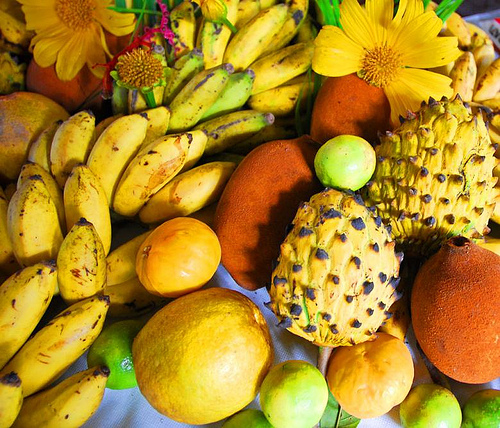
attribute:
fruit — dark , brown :
[190, 139, 437, 338]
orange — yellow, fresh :
[134, 215, 221, 295]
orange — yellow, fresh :
[132, 289, 281, 427]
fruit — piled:
[265, 183, 405, 350]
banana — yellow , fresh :
[96, 115, 197, 215]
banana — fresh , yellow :
[113, 128, 192, 223]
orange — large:
[125, 282, 278, 427]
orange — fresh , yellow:
[134, 288, 273, 423]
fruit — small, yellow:
[256, 358, 328, 425]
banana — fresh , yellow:
[206, 0, 336, 97]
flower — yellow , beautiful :
[309, 0, 457, 125]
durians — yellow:
[215, 173, 487, 333]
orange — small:
[153, 234, 214, 276]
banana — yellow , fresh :
[16, 164, 104, 296]